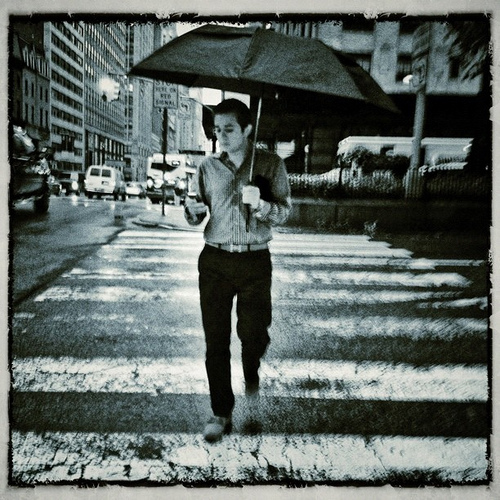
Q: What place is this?
A: It is a street.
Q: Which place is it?
A: It is a street.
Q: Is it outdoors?
A: Yes, it is outdoors.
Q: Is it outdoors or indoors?
A: It is outdoors.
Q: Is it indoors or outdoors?
A: It is outdoors.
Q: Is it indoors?
A: No, it is outdoors.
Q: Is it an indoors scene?
A: No, it is outdoors.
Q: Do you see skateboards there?
A: No, there are no skateboards.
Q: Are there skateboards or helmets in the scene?
A: No, there are no skateboards or helmets.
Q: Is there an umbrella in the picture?
A: Yes, there is an umbrella.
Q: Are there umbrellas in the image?
A: Yes, there is an umbrella.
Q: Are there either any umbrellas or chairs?
A: Yes, there is an umbrella.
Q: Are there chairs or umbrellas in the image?
A: Yes, there is an umbrella.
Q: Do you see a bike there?
A: No, there are no bikes.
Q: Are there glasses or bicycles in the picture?
A: No, there are no bicycles or glasses.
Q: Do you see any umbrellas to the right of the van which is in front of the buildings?
A: Yes, there is an umbrella to the right of the van.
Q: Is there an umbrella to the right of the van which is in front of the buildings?
A: Yes, there is an umbrella to the right of the van.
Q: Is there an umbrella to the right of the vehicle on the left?
A: Yes, there is an umbrella to the right of the van.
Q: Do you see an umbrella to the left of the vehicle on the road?
A: No, the umbrella is to the right of the van.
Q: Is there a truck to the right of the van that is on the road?
A: No, there is an umbrella to the right of the van.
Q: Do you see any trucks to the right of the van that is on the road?
A: No, there is an umbrella to the right of the van.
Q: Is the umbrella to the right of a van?
A: Yes, the umbrella is to the right of a van.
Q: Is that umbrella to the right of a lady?
A: No, the umbrella is to the right of a van.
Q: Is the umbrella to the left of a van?
A: No, the umbrella is to the right of a van.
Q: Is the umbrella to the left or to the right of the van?
A: The umbrella is to the right of the van.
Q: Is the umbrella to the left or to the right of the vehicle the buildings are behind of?
A: The umbrella is to the right of the van.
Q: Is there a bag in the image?
A: No, there are no bags.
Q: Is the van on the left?
A: Yes, the van is on the left of the image.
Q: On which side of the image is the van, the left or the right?
A: The van is on the left of the image.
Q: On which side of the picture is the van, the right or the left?
A: The van is on the left of the image.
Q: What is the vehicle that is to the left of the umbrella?
A: The vehicle is a van.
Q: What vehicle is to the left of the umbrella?
A: The vehicle is a van.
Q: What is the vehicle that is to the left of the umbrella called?
A: The vehicle is a van.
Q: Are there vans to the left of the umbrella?
A: Yes, there is a van to the left of the umbrella.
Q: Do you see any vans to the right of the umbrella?
A: No, the van is to the left of the umbrella.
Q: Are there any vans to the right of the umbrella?
A: No, the van is to the left of the umbrella.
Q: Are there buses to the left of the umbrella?
A: No, there is a van to the left of the umbrella.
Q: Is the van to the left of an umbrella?
A: Yes, the van is to the left of an umbrella.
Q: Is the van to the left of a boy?
A: No, the van is to the left of an umbrella.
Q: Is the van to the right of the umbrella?
A: No, the van is to the left of the umbrella.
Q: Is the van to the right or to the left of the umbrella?
A: The van is to the left of the umbrella.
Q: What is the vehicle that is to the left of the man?
A: The vehicle is a van.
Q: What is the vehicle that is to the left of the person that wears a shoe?
A: The vehicle is a van.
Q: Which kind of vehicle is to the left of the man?
A: The vehicle is a van.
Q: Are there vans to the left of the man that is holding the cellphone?
A: Yes, there is a van to the left of the man.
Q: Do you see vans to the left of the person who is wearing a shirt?
A: Yes, there is a van to the left of the man.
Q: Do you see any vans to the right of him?
A: No, the van is to the left of the man.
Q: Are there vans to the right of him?
A: No, the van is to the left of the man.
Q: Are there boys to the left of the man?
A: No, there is a van to the left of the man.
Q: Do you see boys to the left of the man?
A: No, there is a van to the left of the man.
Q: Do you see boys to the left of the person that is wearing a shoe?
A: No, there is a van to the left of the man.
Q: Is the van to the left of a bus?
A: No, the van is to the left of a man.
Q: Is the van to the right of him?
A: No, the van is to the left of a man.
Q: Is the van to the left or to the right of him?
A: The van is to the left of the man.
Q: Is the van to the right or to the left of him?
A: The van is to the left of the man.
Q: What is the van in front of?
A: The van is in front of the buildings.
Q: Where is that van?
A: The van is on the road.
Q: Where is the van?
A: The van is on the road.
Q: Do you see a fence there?
A: Yes, there is a fence.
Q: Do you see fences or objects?
A: Yes, there is a fence.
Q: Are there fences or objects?
A: Yes, there is a fence.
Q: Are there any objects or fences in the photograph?
A: Yes, there is a fence.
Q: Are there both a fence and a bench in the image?
A: No, there is a fence but no benches.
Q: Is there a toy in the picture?
A: No, there are no toys.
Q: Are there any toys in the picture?
A: No, there are no toys.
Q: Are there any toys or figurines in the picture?
A: No, there are no toys or figurines.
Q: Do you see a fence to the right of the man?
A: Yes, there is a fence to the right of the man.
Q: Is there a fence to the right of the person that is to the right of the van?
A: Yes, there is a fence to the right of the man.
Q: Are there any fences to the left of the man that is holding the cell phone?
A: No, the fence is to the right of the man.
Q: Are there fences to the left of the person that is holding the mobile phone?
A: No, the fence is to the right of the man.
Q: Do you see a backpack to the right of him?
A: No, there is a fence to the right of the man.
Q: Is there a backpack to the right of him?
A: No, there is a fence to the right of the man.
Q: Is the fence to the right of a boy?
A: No, the fence is to the right of the man.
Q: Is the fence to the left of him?
A: No, the fence is to the right of a man.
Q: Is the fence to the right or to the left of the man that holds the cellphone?
A: The fence is to the right of the man.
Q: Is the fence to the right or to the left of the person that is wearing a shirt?
A: The fence is to the right of the man.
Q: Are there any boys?
A: No, there are no boys.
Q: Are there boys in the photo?
A: No, there are no boys.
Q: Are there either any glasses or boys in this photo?
A: No, there are no boys or glasses.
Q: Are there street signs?
A: Yes, there is a street sign.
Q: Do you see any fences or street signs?
A: Yes, there is a street sign.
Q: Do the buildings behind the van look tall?
A: Yes, the buildings are tall.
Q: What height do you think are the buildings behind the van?
A: The buildings are tall.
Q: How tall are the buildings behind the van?
A: The buildings are tall.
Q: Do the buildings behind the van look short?
A: No, the buildings are tall.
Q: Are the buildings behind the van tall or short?
A: The buildings are tall.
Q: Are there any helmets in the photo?
A: No, there are no helmets.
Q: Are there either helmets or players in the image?
A: No, there are no helmets or players.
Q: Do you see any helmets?
A: No, there are no helmets.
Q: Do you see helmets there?
A: No, there are no helmets.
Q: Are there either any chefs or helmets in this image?
A: No, there are no helmets or chefs.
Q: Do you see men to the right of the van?
A: Yes, there is a man to the right of the van.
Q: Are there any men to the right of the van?
A: Yes, there is a man to the right of the van.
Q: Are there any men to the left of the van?
A: No, the man is to the right of the van.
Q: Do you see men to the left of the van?
A: No, the man is to the right of the van.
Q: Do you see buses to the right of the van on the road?
A: No, there is a man to the right of the van.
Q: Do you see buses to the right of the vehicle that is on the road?
A: No, there is a man to the right of the van.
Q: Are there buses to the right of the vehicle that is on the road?
A: No, there is a man to the right of the van.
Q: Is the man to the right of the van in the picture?
A: Yes, the man is to the right of the van.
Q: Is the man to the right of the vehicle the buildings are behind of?
A: Yes, the man is to the right of the van.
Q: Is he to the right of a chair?
A: No, the man is to the right of the van.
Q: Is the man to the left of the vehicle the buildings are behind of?
A: No, the man is to the right of the van.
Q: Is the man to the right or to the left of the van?
A: The man is to the right of the van.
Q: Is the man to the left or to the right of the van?
A: The man is to the right of the van.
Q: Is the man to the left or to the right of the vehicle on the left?
A: The man is to the right of the van.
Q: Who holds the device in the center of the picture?
A: The man holds the cell phone.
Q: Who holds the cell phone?
A: The man holds the cell phone.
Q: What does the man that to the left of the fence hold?
A: The man holds the mobile phone.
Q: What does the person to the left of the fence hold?
A: The man holds the mobile phone.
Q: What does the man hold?
A: The man holds the mobile phone.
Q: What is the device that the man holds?
A: The device is a cell phone.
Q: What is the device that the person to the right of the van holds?
A: The device is a cell phone.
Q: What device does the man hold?
A: The man holds the mobile phone.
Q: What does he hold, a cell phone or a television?
A: The man holds a cell phone.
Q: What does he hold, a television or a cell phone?
A: The man holds a cell phone.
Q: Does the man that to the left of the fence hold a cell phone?
A: Yes, the man holds a cell phone.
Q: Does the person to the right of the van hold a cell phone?
A: Yes, the man holds a cell phone.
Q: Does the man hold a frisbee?
A: No, the man holds a cell phone.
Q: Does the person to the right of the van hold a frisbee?
A: No, the man holds a cell phone.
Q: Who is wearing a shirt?
A: The man is wearing a shirt.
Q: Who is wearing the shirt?
A: The man is wearing a shirt.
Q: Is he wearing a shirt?
A: Yes, the man is wearing a shirt.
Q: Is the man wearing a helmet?
A: No, the man is wearing a shirt.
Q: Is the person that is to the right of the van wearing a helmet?
A: No, the man is wearing a shirt.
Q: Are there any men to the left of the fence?
A: Yes, there is a man to the left of the fence.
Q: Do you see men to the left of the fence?
A: Yes, there is a man to the left of the fence.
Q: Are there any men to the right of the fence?
A: No, the man is to the left of the fence.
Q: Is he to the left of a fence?
A: Yes, the man is to the left of a fence.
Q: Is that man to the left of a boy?
A: No, the man is to the left of a fence.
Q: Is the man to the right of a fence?
A: No, the man is to the left of a fence.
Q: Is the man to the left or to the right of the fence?
A: The man is to the left of the fence.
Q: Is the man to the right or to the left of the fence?
A: The man is to the left of the fence.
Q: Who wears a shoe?
A: The man wears a shoe.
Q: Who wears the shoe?
A: The man wears a shoe.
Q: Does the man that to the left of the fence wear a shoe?
A: Yes, the man wears a shoe.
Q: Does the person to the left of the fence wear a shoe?
A: Yes, the man wears a shoe.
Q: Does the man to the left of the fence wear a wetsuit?
A: No, the man wears a shoe.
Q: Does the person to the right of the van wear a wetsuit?
A: No, the man wears a shoe.